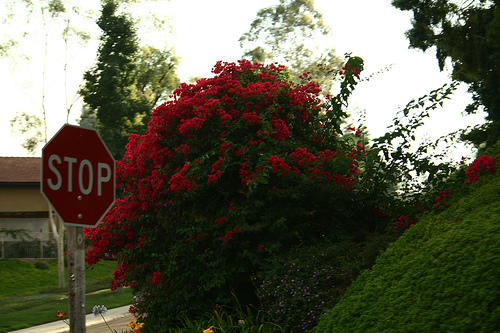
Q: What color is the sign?
A: Red.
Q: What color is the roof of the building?
A: Brown.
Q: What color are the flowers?
A: Red.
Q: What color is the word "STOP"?
A: White.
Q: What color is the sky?
A: White.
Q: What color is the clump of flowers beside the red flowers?
A: Purple.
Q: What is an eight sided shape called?
A: Octagon.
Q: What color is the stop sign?
A: Red.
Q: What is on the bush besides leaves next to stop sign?
A: Flowers.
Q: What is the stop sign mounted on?
A: Pole.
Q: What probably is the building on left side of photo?
A: House.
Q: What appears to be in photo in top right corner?
A: Tree.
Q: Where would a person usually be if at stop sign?
A: In vehicle.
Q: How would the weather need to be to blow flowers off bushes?
A: Windy.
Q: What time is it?
A: Afternoon.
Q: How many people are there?
A: None.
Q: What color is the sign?
A: Red and white.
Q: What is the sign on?
A: A wooden post.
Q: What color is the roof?
A: Brown.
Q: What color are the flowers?
A: Red.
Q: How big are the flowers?
A: Tiny.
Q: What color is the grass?
A: Green.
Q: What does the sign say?
A: Stop.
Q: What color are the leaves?
A: Green.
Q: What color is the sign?
A: Red.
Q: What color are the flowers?
A: Red.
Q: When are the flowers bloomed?
A: Spring time.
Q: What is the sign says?
A: STOP.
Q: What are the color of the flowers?
A: Red.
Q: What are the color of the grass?
A: Green.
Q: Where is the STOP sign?
A: Beside the bushes.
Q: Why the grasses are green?
A: It's springtime.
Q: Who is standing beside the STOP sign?
A: No one.